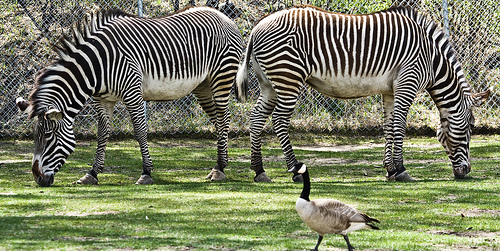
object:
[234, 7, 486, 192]
zebra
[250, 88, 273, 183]
leg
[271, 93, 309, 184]
leg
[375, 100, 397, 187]
leg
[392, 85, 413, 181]
leg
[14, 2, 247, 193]
zebra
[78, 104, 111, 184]
leg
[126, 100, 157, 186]
leg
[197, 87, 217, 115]
leg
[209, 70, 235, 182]
leg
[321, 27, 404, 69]
stripes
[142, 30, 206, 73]
stripes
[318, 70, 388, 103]
underbelly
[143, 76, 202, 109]
underbelly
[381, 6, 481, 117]
mane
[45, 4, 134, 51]
mane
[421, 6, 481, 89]
stripes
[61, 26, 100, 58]
stripes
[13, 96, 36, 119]
ear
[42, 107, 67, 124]
ear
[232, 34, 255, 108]
tail